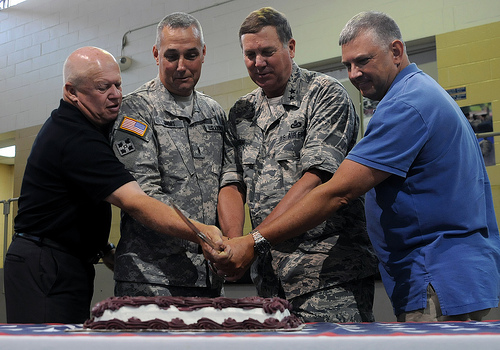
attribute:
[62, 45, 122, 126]
head — bald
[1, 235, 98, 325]
pants — black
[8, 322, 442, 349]
table — US flag themed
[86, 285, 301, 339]
icing — white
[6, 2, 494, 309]
wall — yellow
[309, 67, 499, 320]
shirt — blue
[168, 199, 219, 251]
metal point — sharp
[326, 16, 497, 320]
men — smiling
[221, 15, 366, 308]
men — smiling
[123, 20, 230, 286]
men — smiling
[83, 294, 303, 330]
icing — brown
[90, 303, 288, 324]
frosting — white